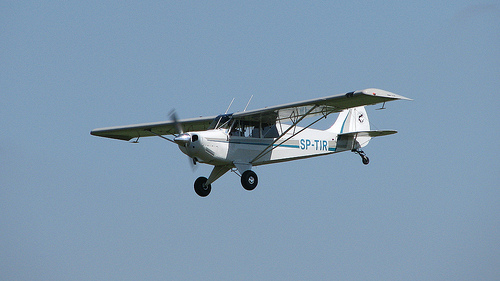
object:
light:
[372, 92, 376, 95]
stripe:
[207, 137, 339, 151]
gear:
[247, 177, 256, 185]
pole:
[245, 104, 338, 165]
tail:
[328, 105, 399, 165]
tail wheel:
[362, 157, 370, 165]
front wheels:
[193, 176, 211, 197]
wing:
[90, 88, 414, 142]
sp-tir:
[300, 139, 327, 151]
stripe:
[339, 110, 352, 134]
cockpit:
[220, 116, 285, 140]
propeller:
[160, 109, 218, 175]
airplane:
[89, 88, 416, 197]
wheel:
[361, 156, 370, 165]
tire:
[240, 170, 259, 191]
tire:
[193, 176, 212, 197]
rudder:
[335, 107, 374, 153]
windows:
[232, 121, 281, 139]